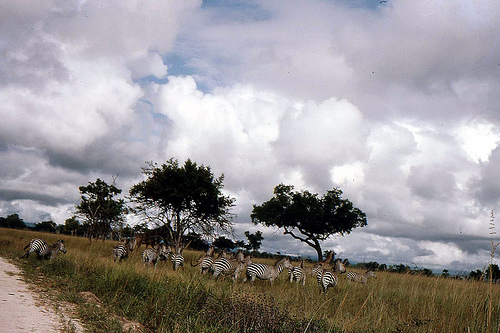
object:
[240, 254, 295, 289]
zebra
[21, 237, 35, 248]
zebras tail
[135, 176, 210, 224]
tree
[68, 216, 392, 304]
zebras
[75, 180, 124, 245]
green trees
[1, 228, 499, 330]
large field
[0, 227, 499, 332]
grassy field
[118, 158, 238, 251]
green trees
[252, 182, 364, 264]
green trees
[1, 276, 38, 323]
road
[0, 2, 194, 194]
grey cloud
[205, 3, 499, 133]
grey cloud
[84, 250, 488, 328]
tall grass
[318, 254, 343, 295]
zebra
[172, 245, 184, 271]
zebra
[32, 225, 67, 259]
zebra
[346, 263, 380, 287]
zebra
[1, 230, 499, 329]
field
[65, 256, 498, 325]
grass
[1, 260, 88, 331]
dirt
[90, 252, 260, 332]
field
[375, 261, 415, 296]
grass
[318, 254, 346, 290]
zebra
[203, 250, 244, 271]
zebra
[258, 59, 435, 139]
sky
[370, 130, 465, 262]
clouds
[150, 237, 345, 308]
zebras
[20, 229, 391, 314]
zebras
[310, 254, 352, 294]
zebra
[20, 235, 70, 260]
zebra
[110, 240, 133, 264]
zebra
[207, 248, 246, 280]
zebra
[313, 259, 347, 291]
zebra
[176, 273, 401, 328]
grass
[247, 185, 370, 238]
branch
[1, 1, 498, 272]
sky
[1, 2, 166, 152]
clouds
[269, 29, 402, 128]
clouds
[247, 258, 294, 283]
zebra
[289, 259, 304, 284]
zebra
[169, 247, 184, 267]
zebra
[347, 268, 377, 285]
zebra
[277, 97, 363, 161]
clouds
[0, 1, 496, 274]
clouds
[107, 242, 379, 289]
zebras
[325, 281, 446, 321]
grass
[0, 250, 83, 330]
dirt road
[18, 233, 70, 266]
zebra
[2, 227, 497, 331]
grass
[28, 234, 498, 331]
grass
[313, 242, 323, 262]
tree trunk